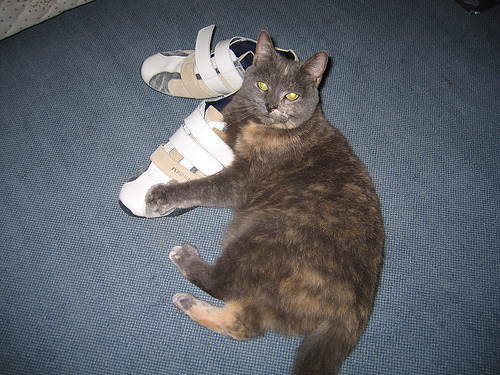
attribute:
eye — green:
[276, 74, 305, 123]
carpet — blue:
[32, 37, 232, 373]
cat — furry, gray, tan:
[161, 24, 393, 344]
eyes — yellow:
[245, 73, 312, 103]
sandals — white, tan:
[98, 35, 278, 213]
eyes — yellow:
[252, 68, 302, 104]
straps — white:
[161, 106, 241, 178]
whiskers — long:
[216, 93, 336, 145]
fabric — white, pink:
[1, 0, 61, 34]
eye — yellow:
[278, 86, 305, 113]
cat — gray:
[174, 20, 383, 372]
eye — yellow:
[243, 68, 279, 106]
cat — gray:
[161, 24, 401, 371]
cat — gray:
[156, 31, 386, 360]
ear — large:
[292, 44, 332, 91]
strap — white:
[211, 35, 246, 94]